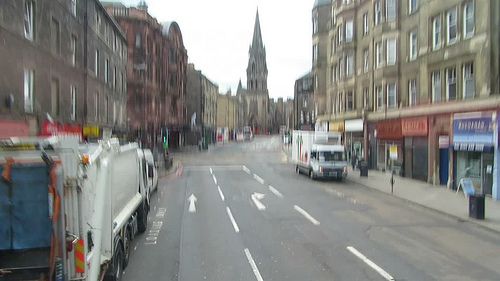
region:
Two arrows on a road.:
[157, 170, 287, 271]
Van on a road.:
[272, 120, 367, 215]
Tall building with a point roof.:
[210, 1, 290, 161]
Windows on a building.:
[411, 5, 483, 65]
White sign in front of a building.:
[447, 130, 477, 195]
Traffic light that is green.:
[151, 120, 173, 155]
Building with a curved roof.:
[150, 10, 190, 157]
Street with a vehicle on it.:
[126, 127, 491, 273]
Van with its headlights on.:
[290, 125, 350, 185]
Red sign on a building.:
[369, 111, 431, 175]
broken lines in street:
[214, 179, 346, 279]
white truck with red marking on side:
[291, 128, 353, 189]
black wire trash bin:
[468, 186, 495, 222]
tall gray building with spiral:
[241, 3, 281, 123]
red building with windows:
[126, 8, 172, 130]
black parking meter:
[384, 163, 401, 198]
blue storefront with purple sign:
[444, 110, 495, 191]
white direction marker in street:
[240, 188, 283, 220]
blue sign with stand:
[453, 173, 476, 198]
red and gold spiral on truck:
[70, 236, 92, 275]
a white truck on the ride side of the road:
[288, 125, 355, 184]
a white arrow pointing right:
[248, 187, 269, 217]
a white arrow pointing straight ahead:
[184, 184, 202, 219]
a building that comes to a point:
[246, 0, 276, 135]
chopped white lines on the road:
[202, 156, 267, 279]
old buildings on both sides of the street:
[7, 8, 499, 118]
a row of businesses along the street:
[306, 112, 499, 179]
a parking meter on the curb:
[383, 156, 403, 201]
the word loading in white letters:
[142, 218, 167, 253]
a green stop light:
[157, 125, 175, 168]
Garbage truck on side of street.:
[1, 132, 151, 276]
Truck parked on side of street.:
[282, 123, 360, 187]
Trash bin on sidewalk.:
[461, 186, 492, 228]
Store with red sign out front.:
[371, 111, 433, 146]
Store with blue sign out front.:
[447, 104, 499, 154]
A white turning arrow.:
[231, 178, 290, 223]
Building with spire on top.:
[236, 2, 283, 124]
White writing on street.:
[139, 203, 174, 257]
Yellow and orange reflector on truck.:
[69, 232, 101, 277]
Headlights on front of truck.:
[316, 162, 351, 176]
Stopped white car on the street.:
[286, 127, 351, 181]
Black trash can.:
[458, 173, 491, 221]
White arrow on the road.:
[182, 190, 203, 219]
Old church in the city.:
[241, 3, 294, 138]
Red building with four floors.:
[116, 5, 200, 159]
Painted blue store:
[451, 112, 498, 194]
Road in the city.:
[176, 147, 304, 279]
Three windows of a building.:
[420, 62, 486, 102]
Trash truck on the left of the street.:
[4, 126, 169, 277]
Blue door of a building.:
[432, 128, 453, 185]